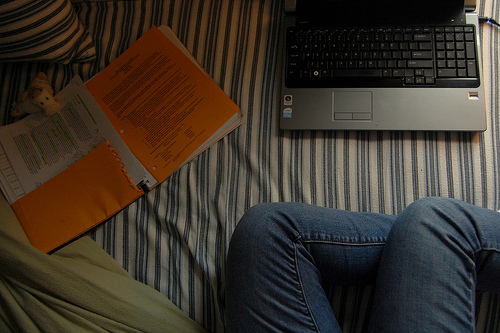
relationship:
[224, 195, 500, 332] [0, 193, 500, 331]
legs of person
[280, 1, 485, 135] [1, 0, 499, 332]
laptop on bed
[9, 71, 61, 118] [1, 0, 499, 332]
stuff cow on bed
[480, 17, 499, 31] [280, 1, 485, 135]
cable in laptop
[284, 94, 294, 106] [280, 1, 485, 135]
sticker on laptop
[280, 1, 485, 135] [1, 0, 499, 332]
laptop kept in bed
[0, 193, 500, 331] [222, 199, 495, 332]
person wearing blue jeans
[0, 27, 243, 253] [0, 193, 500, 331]
folder near person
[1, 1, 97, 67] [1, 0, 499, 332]
pillow in bed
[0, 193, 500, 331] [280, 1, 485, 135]
person with a laptop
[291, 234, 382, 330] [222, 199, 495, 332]
inseam of jeans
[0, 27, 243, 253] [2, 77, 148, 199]
folder holding papers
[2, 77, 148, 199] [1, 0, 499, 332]
papers laying on bed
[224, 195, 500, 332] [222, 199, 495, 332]
legs wearing blue jeans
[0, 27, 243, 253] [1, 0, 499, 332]
folder on bed